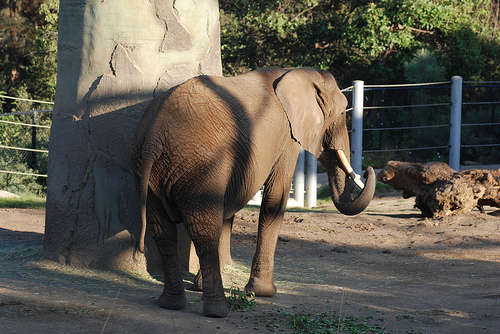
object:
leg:
[175, 159, 232, 301]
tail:
[139, 132, 163, 253]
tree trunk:
[376, 160, 500, 219]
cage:
[2, 75, 496, 330]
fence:
[1, 75, 498, 211]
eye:
[341, 111, 344, 114]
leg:
[133, 172, 187, 290]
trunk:
[318, 114, 376, 216]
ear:
[275, 67, 330, 158]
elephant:
[130, 65, 377, 317]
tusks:
[335, 149, 365, 190]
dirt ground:
[284, 213, 484, 332]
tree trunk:
[43, 1, 138, 266]